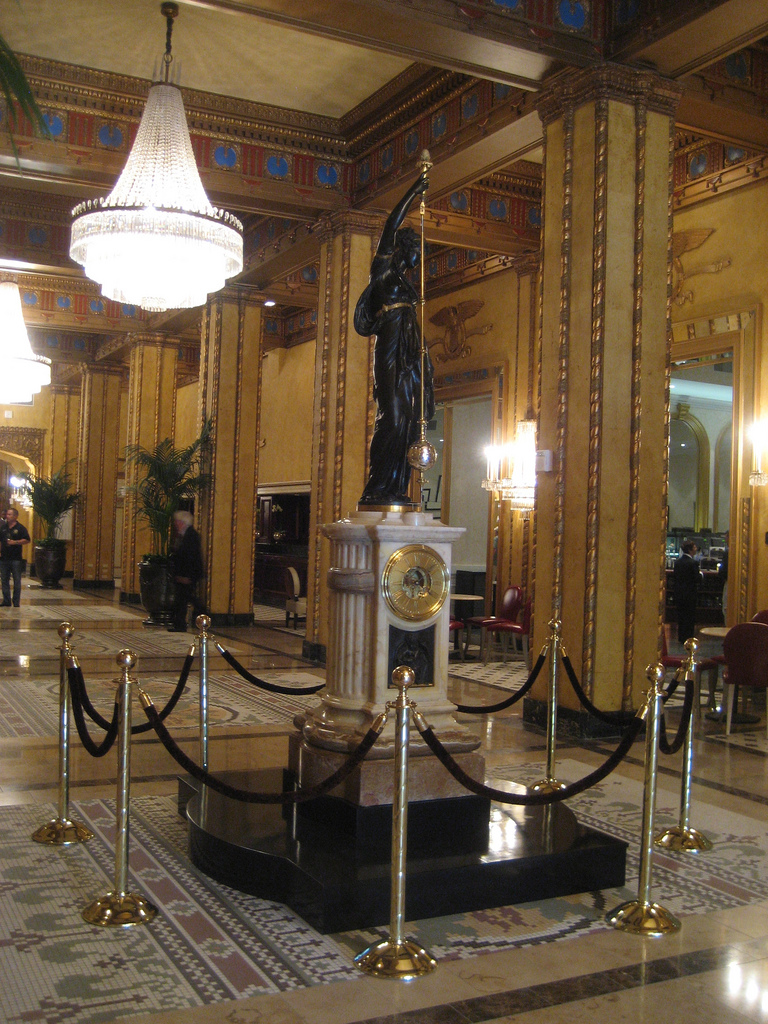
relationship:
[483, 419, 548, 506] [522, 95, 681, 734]
light behind pillar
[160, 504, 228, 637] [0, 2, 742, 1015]
man in room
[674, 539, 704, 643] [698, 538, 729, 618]
man standing at counter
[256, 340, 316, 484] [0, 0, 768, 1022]
wall on side of a building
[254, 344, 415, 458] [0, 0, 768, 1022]
wall on side of a building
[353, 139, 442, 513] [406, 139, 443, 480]
statue holding rod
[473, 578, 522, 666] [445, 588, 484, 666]
red chair at table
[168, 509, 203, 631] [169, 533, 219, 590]
man in suit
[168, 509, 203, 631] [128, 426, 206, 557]
man standing by plant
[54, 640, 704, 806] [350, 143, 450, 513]
rope to protect statue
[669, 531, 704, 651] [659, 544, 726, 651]
man wearing suit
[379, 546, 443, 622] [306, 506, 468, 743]
clock on column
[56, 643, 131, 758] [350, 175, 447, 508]
rope surrounding statue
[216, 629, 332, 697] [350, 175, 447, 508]
rope surrounding statue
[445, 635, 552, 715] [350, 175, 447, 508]
rope surrounding statue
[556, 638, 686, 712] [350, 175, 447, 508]
rope surrounding statue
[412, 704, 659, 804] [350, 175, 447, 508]
rope surrounding statue